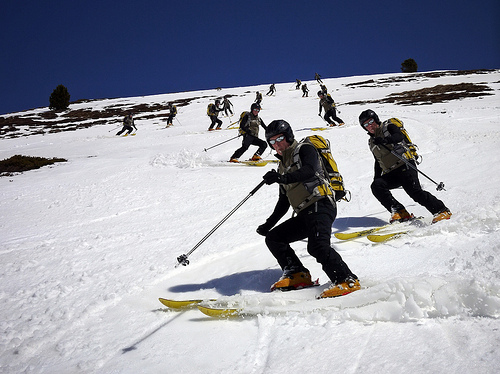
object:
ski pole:
[372, 136, 448, 192]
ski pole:
[201, 132, 246, 153]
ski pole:
[108, 124, 125, 132]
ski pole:
[318, 114, 330, 127]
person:
[228, 102, 272, 164]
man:
[358, 107, 453, 224]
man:
[301, 83, 310, 97]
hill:
[0, 66, 500, 374]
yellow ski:
[366, 231, 404, 243]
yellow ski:
[333, 226, 386, 240]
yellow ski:
[239, 160, 269, 166]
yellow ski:
[158, 296, 218, 309]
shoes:
[313, 275, 364, 300]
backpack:
[298, 133, 353, 202]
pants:
[264, 198, 360, 283]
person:
[316, 89, 345, 127]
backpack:
[383, 116, 423, 166]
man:
[116, 111, 138, 136]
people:
[265, 83, 276, 97]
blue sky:
[0, 0, 497, 117]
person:
[206, 99, 226, 131]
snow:
[239, 304, 411, 369]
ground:
[0, 70, 500, 374]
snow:
[64, 206, 154, 347]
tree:
[400, 57, 419, 73]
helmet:
[264, 119, 295, 151]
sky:
[0, 0, 500, 115]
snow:
[0, 149, 72, 183]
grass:
[0, 154, 68, 176]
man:
[255, 118, 361, 299]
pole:
[171, 168, 282, 271]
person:
[165, 101, 178, 129]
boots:
[270, 267, 313, 292]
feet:
[317, 273, 366, 298]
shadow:
[165, 266, 287, 298]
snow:
[1, 61, 500, 374]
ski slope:
[0, 65, 500, 370]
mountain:
[0, 67, 500, 374]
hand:
[262, 168, 282, 185]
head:
[264, 119, 294, 157]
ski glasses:
[269, 135, 285, 145]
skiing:
[155, 276, 393, 320]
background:
[0, 65, 500, 182]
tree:
[47, 82, 72, 114]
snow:
[315, 275, 363, 300]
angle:
[166, 164, 362, 345]